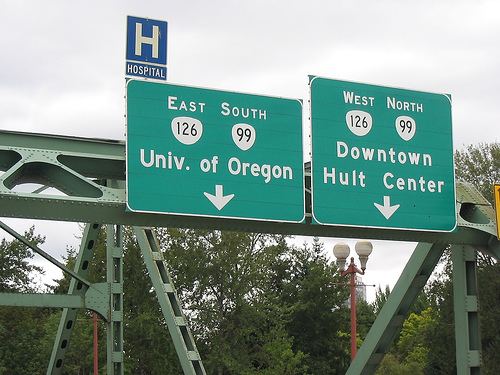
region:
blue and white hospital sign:
[123, 11, 168, 82]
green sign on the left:
[123, 83, 305, 227]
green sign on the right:
[308, 78, 458, 233]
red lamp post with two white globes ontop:
[325, 240, 378, 364]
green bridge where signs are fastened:
[3, 128, 496, 238]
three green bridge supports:
[65, 226, 203, 371]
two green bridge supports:
[349, 242, 482, 373]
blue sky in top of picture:
[3, 9, 494, 127]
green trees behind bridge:
[161, 233, 331, 373]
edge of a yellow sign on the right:
[492, 178, 498, 238]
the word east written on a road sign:
[163, 94, 208, 113]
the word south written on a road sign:
[218, 97, 271, 123]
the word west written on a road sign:
[342, 90, 378, 106]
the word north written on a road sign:
[385, 93, 425, 113]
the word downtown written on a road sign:
[331, 141, 431, 169]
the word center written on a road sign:
[378, 168, 448, 193]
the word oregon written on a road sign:
[225, 155, 304, 185]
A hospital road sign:
[124, 13, 169, 81]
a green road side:
[306, 72, 464, 230]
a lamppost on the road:
[324, 240, 383, 366]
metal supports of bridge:
[19, 94, 483, 357]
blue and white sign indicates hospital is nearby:
[112, 8, 187, 83]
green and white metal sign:
[125, 77, 309, 237]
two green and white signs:
[113, 65, 463, 260]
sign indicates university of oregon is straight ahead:
[120, 78, 310, 248]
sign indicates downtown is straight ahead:
[305, 62, 474, 269]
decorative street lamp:
[327, 238, 394, 368]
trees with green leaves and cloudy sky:
[11, 95, 313, 353]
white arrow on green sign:
[371, 191, 408, 231]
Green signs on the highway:
[1, 6, 497, 373]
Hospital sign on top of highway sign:
[122, 14, 167, 82]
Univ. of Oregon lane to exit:
[125, 77, 305, 222]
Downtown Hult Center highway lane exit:
[309, 75, 459, 232]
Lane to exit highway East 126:
[165, 91, 208, 146]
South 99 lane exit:
[220, 100, 269, 152]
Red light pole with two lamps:
[330, 235, 371, 360]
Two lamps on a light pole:
[332, 240, 374, 275]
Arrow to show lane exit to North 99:
[372, 192, 402, 222]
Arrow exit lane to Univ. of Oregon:
[200, 179, 240, 212]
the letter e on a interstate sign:
[105, 71, 314, 258]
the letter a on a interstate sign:
[111, 95, 308, 250]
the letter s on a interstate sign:
[91, 96, 315, 259]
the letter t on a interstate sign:
[107, 86, 305, 251]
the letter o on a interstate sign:
[95, 81, 297, 251]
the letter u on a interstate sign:
[93, 86, 304, 258]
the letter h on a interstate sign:
[300, 94, 486, 218]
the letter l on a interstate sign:
[298, 89, 462, 263]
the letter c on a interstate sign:
[263, 108, 457, 281]